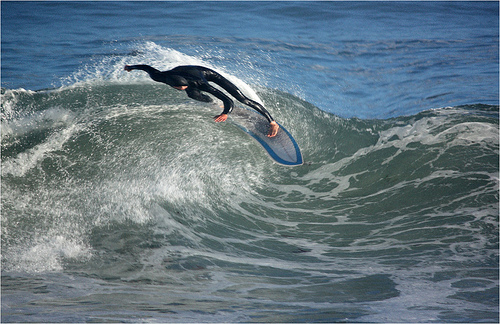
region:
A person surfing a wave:
[115, 43, 306, 174]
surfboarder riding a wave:
[124, 49, 301, 167]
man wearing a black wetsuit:
[130, 57, 302, 167]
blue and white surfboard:
[232, 101, 303, 171]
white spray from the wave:
[7, 87, 135, 238]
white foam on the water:
[351, 246, 433, 323]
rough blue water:
[16, 10, 463, 105]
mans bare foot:
[266, 119, 279, 138]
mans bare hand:
[209, 109, 230, 122]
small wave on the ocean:
[5, 45, 493, 211]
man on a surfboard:
[139, 55, 307, 170]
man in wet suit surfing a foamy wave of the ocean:
[117, 56, 282, 144]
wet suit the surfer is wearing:
[127, 56, 272, 123]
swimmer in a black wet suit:
[120, 53, 282, 140]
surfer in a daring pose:
[121, 59, 283, 139]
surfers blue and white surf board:
[217, 99, 304, 171]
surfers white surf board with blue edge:
[213, 94, 304, 168]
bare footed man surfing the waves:
[120, 57, 281, 141]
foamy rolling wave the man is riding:
[0, 33, 497, 280]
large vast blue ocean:
[0, 1, 497, 321]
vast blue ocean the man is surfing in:
[3, 2, 498, 322]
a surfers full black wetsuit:
[123, 64, 275, 124]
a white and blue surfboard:
[230, 112, 304, 168]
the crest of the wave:
[1, 72, 127, 103]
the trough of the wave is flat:
[221, 166, 427, 256]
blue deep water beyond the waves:
[322, 1, 499, 106]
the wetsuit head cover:
[170, 73, 189, 87]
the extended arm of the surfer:
[122, 62, 169, 84]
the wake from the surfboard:
[240, 67, 271, 104]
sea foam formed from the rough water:
[374, 115, 499, 170]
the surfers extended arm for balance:
[121, 59, 171, 84]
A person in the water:
[111, 47, 310, 147]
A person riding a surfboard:
[114, 50, 326, 189]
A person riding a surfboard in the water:
[120, 42, 326, 192]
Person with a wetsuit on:
[114, 50, 302, 146]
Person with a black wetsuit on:
[111, 41, 315, 148]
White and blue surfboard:
[257, 145, 312, 185]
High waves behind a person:
[40, 29, 257, 118]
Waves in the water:
[322, 50, 477, 180]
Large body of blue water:
[302, 22, 452, 93]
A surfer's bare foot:
[262, 117, 286, 141]